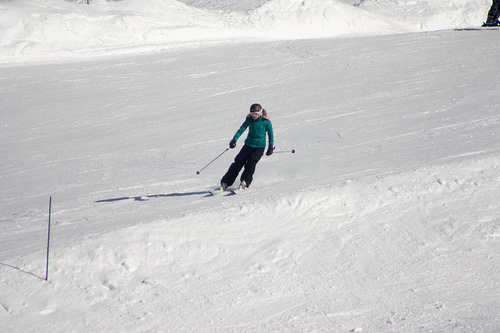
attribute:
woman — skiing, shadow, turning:
[162, 79, 308, 228]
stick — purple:
[23, 176, 72, 284]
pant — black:
[207, 148, 277, 192]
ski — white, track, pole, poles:
[178, 174, 260, 201]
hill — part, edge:
[65, 102, 172, 243]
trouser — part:
[244, 138, 277, 162]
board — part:
[223, 174, 260, 206]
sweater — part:
[256, 127, 267, 139]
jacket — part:
[252, 133, 265, 144]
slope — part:
[375, 49, 460, 133]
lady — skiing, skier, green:
[208, 115, 288, 166]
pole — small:
[172, 143, 238, 182]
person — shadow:
[93, 174, 211, 220]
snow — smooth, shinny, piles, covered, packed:
[326, 53, 441, 167]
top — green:
[231, 131, 275, 156]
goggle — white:
[250, 108, 255, 120]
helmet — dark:
[241, 107, 263, 122]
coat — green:
[230, 116, 281, 156]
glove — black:
[221, 135, 243, 154]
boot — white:
[209, 172, 250, 198]